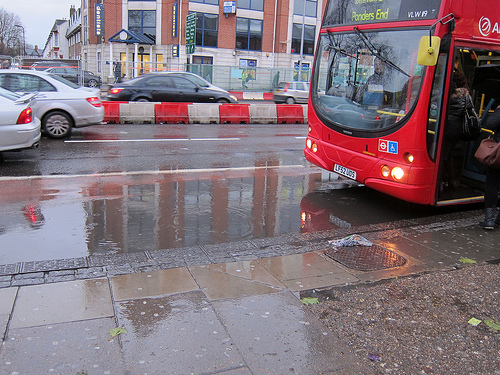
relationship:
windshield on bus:
[320, 29, 427, 129] [304, 0, 488, 208]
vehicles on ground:
[0, 64, 236, 155] [0, 123, 499, 374]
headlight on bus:
[390, 165, 404, 181] [304, 0, 488, 208]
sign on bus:
[356, 107, 417, 178] [283, 9, 493, 228]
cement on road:
[94, 163, 308, 254] [11, 146, 361, 233]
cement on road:
[94, 163, 308, 254] [3, 119, 427, 259]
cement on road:
[4, 119, 499, 374] [2, 112, 498, 277]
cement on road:
[94, 163, 308, 254] [0, 122, 410, 268]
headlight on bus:
[379, 162, 406, 182] [304, 0, 488, 208]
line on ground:
[3, 158, 305, 179] [0, 123, 499, 374]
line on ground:
[63, 132, 240, 143] [0, 123, 499, 374]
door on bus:
[431, 36, 498, 214] [304, 0, 488, 208]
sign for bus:
[344, 5, 395, 30] [301, 3, 497, 223]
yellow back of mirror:
[416, 31, 440, 66] [416, 34, 441, 70]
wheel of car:
[28, 106, 75, 142] [0, 65, 106, 140]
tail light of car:
[14, 101, 37, 127] [0, 82, 44, 167]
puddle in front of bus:
[0, 173, 414, 260] [285, 4, 496, 211]